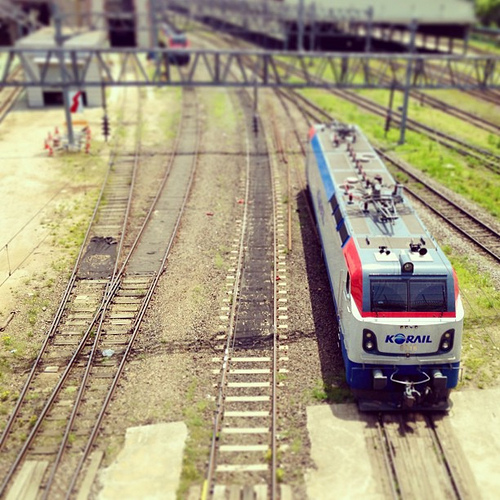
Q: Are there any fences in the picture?
A: No, there are no fences.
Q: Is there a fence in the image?
A: No, there are no fences.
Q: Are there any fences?
A: No, there are no fences.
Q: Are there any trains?
A: Yes, there is a train.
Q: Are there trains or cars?
A: Yes, there is a train.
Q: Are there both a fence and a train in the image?
A: No, there is a train but no fences.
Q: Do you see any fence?
A: No, there are no fences.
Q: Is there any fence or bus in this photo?
A: No, there are no fences or buses.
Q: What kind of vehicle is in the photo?
A: The vehicle is a train.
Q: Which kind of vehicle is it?
A: The vehicle is a train.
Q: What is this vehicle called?
A: This is a train.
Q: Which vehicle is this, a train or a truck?
A: This is a train.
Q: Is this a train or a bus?
A: This is a train.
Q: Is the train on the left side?
A: No, the train is on the right of the image.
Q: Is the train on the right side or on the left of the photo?
A: The train is on the right of the image.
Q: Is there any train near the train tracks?
A: Yes, there is a train near the train tracks.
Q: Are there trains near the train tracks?
A: Yes, there is a train near the train tracks.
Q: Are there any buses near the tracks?
A: No, there is a train near the tracks.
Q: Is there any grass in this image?
A: Yes, there is grass.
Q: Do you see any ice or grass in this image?
A: Yes, there is grass.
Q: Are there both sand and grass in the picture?
A: No, there is grass but no sand.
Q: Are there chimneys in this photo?
A: No, there are no chimneys.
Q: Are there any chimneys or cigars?
A: No, there are no chimneys or cigars.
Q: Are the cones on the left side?
A: Yes, the cones are on the left of the image.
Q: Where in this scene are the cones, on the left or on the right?
A: The cones are on the left of the image.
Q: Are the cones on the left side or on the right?
A: The cones are on the left of the image.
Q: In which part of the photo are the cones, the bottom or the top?
A: The cones are in the top of the image.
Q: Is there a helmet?
A: No, there are no helmets.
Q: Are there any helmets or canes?
A: No, there are no helmets or canes.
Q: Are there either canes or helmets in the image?
A: No, there are no helmets or canes.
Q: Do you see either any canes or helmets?
A: No, there are no helmets or canes.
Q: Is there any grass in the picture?
A: Yes, there is grass.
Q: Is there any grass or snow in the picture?
A: Yes, there is grass.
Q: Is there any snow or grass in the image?
A: Yes, there is grass.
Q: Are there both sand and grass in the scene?
A: No, there is grass but no sand.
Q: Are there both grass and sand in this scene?
A: No, there is grass but no sand.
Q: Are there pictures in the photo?
A: No, there are no pictures.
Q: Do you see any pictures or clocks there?
A: No, there are no pictures or clocks.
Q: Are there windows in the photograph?
A: Yes, there is a window.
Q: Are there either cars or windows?
A: Yes, there is a window.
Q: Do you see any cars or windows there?
A: Yes, there is a window.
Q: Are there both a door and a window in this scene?
A: No, there is a window but no doors.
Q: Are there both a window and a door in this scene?
A: No, there is a window but no doors.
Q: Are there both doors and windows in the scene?
A: No, there is a window but no doors.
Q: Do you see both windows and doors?
A: No, there is a window but no doors.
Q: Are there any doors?
A: No, there are no doors.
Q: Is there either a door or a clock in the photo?
A: No, there are no doors or clocks.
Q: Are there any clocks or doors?
A: No, there are no doors or clocks.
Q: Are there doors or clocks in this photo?
A: No, there are no doors or clocks.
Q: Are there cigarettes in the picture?
A: No, there are no cigarettes.